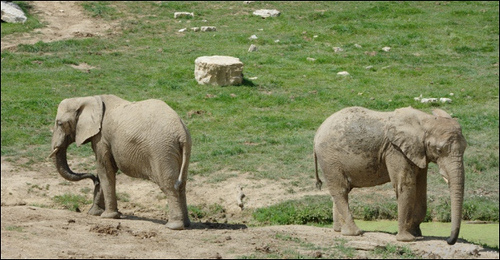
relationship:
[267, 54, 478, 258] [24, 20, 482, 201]
elephant in field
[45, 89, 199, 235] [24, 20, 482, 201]
elephant in field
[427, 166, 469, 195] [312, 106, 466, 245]
tusk on elephant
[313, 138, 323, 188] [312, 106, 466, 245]
tail on elephant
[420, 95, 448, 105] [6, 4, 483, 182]
rock in field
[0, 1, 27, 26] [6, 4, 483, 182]
rock in field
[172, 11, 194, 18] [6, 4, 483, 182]
rock in field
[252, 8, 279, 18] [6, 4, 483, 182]
rock in field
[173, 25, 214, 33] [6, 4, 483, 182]
rock in field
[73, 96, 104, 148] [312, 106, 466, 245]
ear on elephant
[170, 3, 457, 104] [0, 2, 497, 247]
rocks are in field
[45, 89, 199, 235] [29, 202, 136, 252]
elephant standing on dirt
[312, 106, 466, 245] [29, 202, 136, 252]
elephant standing on dirt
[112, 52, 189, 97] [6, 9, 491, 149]
grass in field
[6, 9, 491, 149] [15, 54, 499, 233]
field behind elephants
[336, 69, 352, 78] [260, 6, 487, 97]
rock in lawn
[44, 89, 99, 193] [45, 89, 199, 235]
head of elephant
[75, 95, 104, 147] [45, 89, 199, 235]
ear of elephant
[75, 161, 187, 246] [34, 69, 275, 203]
legs of elephant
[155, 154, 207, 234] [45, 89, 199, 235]
legs of elephant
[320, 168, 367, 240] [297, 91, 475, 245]
legs of elephant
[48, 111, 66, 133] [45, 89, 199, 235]
eye of elephant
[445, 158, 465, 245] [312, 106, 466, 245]
trunk of elephant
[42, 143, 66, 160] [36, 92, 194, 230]
tusks of elephants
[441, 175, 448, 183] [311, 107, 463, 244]
tusk of elephants